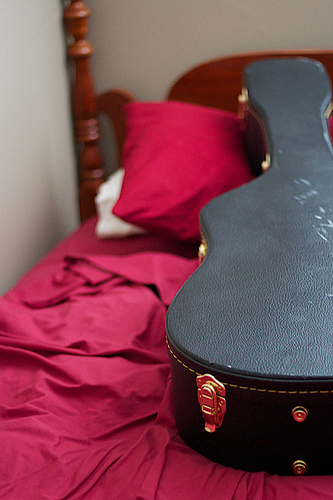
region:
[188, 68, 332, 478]
A black guitar case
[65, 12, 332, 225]
A wooden head board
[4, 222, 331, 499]
A made up bed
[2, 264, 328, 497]
loose red sheets on the bed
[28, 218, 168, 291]
a fitted red sheet on the bed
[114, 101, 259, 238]
A red pillow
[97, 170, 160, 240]
a white pillow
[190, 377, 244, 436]
a latch on the guitar case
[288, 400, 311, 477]
some stands on the bottom of the case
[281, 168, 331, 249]
some white scuffs on the case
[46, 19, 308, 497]
black guitar case on bed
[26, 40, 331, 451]
black guitar case on red sheets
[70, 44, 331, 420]
black guitar case on red pillow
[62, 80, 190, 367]
red pillow on red sheets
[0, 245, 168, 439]
wrinkled red sheets on bed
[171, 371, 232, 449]
metal latch on guitar case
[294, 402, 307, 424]
metal piece on guitar case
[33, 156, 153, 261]
white pillow beneath red one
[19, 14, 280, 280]
brown wooden bed frame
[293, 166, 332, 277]
white scuff marks on case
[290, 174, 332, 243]
white scratches on the guitar case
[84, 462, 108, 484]
wrinkles on the sheet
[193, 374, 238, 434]
a gold latch on the case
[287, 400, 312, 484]
metal grommets on the case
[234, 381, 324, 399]
yellow stitching on the guitar case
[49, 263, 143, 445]
maroon sheets on the bed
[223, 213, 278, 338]
a black leather guitar case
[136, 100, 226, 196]
a fluffy red pillow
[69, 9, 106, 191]
a wooden bed post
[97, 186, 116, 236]
a white pillow underneath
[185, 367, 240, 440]
latch on guitar case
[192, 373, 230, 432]
small golden metal latch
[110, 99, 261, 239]
bright red pillow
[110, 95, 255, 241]
pillow in bright red pillowcase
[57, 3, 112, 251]
post to the headboard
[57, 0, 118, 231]
tall wooden headboard post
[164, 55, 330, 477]
big black guitar case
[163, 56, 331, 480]
large leather container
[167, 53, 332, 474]
protective leather case for a musical instrument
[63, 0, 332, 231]
brown headboard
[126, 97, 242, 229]
Red pillowcase on a pillow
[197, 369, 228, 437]
Buckle on a guitar case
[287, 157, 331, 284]
Scratches on a guitar case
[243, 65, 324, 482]
Black guitar case laying on a bed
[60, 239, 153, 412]
Wrinkled sheet on a bed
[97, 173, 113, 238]
White pillow under another pillow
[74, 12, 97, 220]
Post on headboard of a bed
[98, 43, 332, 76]
Wooden headboard on a bed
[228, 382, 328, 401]
Seam on guitar case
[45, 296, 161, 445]
Maroon sheet on a bed